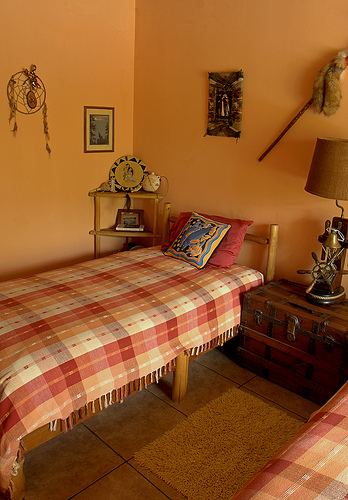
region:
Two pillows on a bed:
[146, 197, 256, 288]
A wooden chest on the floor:
[229, 270, 342, 408]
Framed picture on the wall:
[78, 100, 115, 154]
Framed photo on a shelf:
[93, 199, 154, 237]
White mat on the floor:
[127, 380, 305, 494]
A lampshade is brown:
[298, 132, 345, 207]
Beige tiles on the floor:
[17, 342, 320, 495]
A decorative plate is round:
[102, 147, 147, 193]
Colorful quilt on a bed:
[0, 237, 264, 494]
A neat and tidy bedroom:
[0, 0, 344, 496]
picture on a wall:
[195, 58, 252, 156]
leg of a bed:
[165, 348, 197, 407]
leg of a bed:
[4, 438, 47, 496]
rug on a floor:
[126, 419, 232, 493]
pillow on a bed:
[164, 204, 224, 270]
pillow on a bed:
[219, 243, 241, 269]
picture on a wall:
[76, 91, 122, 151]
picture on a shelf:
[108, 208, 146, 230]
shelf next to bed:
[83, 153, 155, 240]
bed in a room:
[263, 403, 332, 491]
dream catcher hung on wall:
[6, 63, 53, 156]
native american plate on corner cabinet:
[106, 153, 147, 190]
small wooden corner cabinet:
[88, 182, 163, 255]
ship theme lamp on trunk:
[300, 162, 346, 308]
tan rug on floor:
[121, 382, 302, 496]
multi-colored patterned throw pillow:
[164, 208, 230, 268]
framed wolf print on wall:
[81, 103, 114, 153]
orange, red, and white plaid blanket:
[0, 238, 265, 498]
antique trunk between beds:
[236, 278, 346, 406]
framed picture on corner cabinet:
[115, 206, 145, 232]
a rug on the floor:
[148, 387, 255, 466]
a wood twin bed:
[73, 222, 277, 405]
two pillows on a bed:
[179, 205, 245, 275]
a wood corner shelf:
[79, 178, 161, 253]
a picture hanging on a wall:
[81, 93, 124, 160]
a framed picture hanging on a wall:
[181, 61, 250, 144]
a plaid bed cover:
[36, 271, 168, 391]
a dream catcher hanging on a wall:
[2, 56, 54, 120]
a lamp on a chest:
[300, 166, 346, 335]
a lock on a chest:
[284, 312, 301, 349]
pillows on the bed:
[160, 209, 235, 270]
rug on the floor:
[134, 399, 283, 486]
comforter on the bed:
[84, 345, 115, 382]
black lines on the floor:
[107, 449, 130, 474]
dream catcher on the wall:
[3, 59, 54, 156]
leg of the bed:
[169, 349, 190, 409]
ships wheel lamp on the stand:
[292, 131, 346, 313]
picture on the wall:
[202, 67, 245, 145]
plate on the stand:
[109, 152, 145, 192]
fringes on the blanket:
[77, 402, 102, 414]